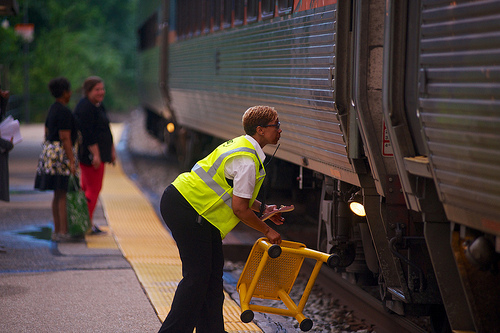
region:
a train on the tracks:
[127, 10, 490, 260]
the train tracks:
[293, 234, 446, 330]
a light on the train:
[340, 190, 368, 209]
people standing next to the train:
[26, 29, 109, 210]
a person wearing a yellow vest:
[154, 71, 331, 316]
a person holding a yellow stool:
[171, 108, 320, 328]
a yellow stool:
[243, 225, 338, 312]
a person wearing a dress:
[35, 73, 77, 193]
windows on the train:
[170, 4, 300, 21]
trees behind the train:
[5, 4, 136, 112]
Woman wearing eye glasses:
[238, 104, 285, 149]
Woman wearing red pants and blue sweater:
[72, 73, 119, 238]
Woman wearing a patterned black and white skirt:
[32, 77, 94, 253]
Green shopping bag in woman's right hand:
[56, 161, 101, 248]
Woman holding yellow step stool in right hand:
[232, 224, 349, 332]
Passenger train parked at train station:
[129, 4, 497, 332]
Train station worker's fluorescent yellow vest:
[168, 137, 269, 236]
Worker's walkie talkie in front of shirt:
[251, 140, 281, 205]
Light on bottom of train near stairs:
[327, 172, 372, 229]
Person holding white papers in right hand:
[0, 114, 27, 149]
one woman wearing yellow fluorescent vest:
[156, 99, 278, 239]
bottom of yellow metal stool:
[230, 233, 337, 331]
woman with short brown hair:
[240, 102, 290, 145]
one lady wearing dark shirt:
[73, 71, 121, 171]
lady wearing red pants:
[72, 73, 112, 230]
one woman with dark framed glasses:
[241, 102, 284, 151]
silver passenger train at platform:
[117, 7, 494, 327]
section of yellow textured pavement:
[91, 122, 255, 332]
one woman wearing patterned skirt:
[36, 74, 78, 198]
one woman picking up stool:
[151, 97, 334, 331]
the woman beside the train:
[139, 88, 326, 332]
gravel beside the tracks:
[307, 288, 367, 330]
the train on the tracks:
[136, 8, 498, 240]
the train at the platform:
[135, 7, 498, 207]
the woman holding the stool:
[166, 97, 338, 332]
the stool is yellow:
[227, 230, 332, 332]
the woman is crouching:
[134, 89, 350, 331]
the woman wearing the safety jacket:
[130, 77, 330, 317]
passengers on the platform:
[26, 63, 118, 255]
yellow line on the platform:
[104, 165, 196, 332]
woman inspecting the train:
[139, 84, 294, 329]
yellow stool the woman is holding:
[226, 232, 341, 327]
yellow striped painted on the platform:
[102, 158, 268, 328]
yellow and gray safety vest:
[168, 131, 265, 238]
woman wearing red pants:
[76, 74, 118, 231]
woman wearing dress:
[21, 76, 91, 247]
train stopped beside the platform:
[123, 2, 495, 332]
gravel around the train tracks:
[134, 124, 376, 331]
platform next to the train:
[3, 127, 248, 331]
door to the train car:
[328, 10, 425, 195]